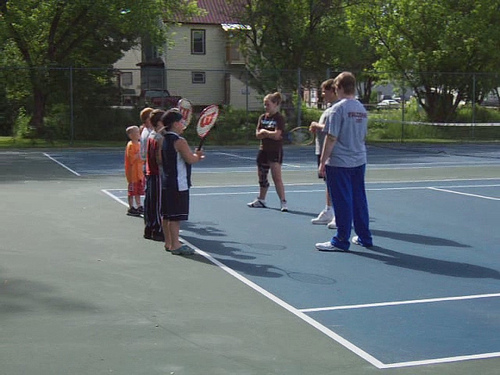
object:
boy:
[125, 125, 147, 217]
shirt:
[125, 141, 145, 183]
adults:
[313, 70, 377, 251]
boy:
[158, 108, 205, 254]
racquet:
[196, 104, 221, 151]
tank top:
[161, 132, 193, 192]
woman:
[248, 91, 288, 211]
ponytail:
[274, 93, 282, 102]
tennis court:
[0, 147, 498, 373]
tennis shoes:
[246, 198, 266, 207]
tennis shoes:
[311, 209, 335, 224]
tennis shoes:
[315, 237, 350, 251]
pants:
[326, 163, 376, 249]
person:
[310, 79, 339, 234]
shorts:
[317, 154, 329, 180]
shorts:
[160, 188, 190, 220]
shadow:
[180, 218, 286, 281]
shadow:
[268, 207, 319, 217]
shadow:
[371, 227, 473, 249]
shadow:
[348, 243, 500, 280]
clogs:
[171, 245, 195, 255]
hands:
[195, 148, 206, 161]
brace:
[257, 163, 270, 187]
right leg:
[258, 159, 271, 199]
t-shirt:
[259, 112, 284, 149]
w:
[200, 112, 217, 128]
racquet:
[176, 98, 193, 130]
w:
[179, 105, 190, 119]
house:
[96, 0, 291, 112]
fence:
[1, 66, 498, 149]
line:
[43, 153, 81, 176]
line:
[100, 189, 129, 206]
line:
[180, 238, 386, 370]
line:
[299, 291, 500, 313]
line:
[382, 343, 500, 371]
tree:
[1, 0, 206, 140]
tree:
[234, 0, 337, 128]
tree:
[369, 1, 500, 127]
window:
[191, 29, 205, 55]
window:
[192, 72, 206, 84]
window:
[121, 72, 132, 85]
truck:
[132, 89, 183, 109]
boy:
[138, 108, 152, 226]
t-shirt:
[323, 99, 368, 168]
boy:
[145, 109, 168, 241]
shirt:
[145, 130, 160, 176]